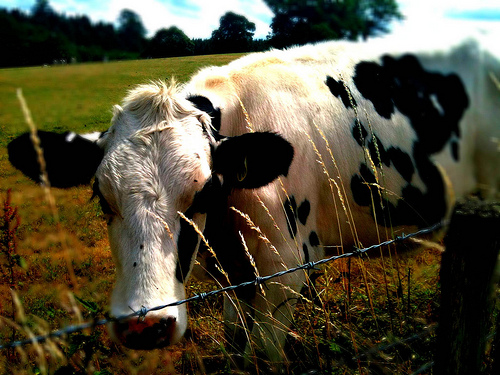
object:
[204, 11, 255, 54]
trees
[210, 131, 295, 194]
ear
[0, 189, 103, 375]
plant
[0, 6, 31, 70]
trees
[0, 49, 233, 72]
horizon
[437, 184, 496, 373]
fence post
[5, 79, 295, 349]
head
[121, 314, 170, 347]
nose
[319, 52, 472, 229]
black spots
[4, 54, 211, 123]
grass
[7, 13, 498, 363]
cow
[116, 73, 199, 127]
hair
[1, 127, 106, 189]
ear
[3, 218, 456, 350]
barbed wire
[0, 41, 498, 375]
field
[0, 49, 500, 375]
pasture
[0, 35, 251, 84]
hill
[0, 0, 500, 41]
sky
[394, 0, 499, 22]
clouds